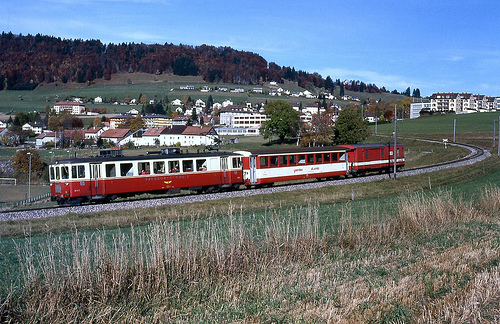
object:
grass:
[0, 180, 500, 324]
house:
[181, 124, 220, 146]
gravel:
[50, 169, 406, 217]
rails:
[0, 133, 484, 214]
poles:
[27, 153, 33, 202]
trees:
[0, 32, 21, 91]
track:
[405, 132, 500, 189]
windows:
[119, 162, 134, 177]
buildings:
[430, 91, 462, 114]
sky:
[0, 0, 500, 98]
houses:
[34, 130, 61, 145]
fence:
[8, 193, 55, 207]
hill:
[381, 111, 500, 135]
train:
[47, 143, 404, 206]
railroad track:
[0, 133, 500, 236]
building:
[410, 98, 431, 119]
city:
[0, 81, 500, 208]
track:
[0, 131, 500, 239]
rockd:
[92, 212, 500, 324]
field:
[0, 79, 500, 320]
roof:
[430, 92, 500, 100]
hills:
[0, 72, 153, 103]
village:
[0, 94, 346, 185]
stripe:
[348, 145, 406, 170]